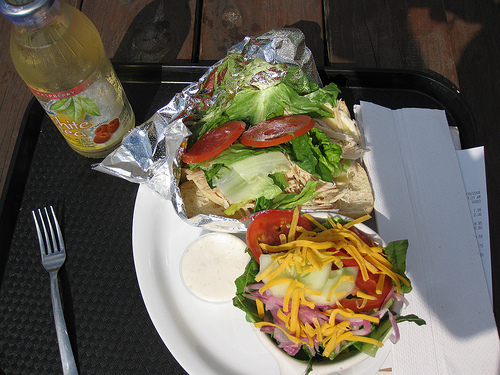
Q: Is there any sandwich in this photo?
A: Yes, there is a sandwich.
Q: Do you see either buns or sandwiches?
A: Yes, there is a sandwich.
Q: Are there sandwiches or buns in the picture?
A: Yes, there is a sandwich.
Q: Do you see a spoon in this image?
A: No, there are no spoons.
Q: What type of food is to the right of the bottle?
A: The food is a sandwich.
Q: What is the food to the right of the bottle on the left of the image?
A: The food is a sandwich.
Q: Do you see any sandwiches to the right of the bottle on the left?
A: Yes, there is a sandwich to the right of the bottle.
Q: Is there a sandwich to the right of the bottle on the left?
A: Yes, there is a sandwich to the right of the bottle.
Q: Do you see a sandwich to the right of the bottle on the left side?
A: Yes, there is a sandwich to the right of the bottle.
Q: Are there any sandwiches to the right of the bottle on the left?
A: Yes, there is a sandwich to the right of the bottle.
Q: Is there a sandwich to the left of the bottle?
A: No, the sandwich is to the right of the bottle.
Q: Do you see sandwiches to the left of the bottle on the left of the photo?
A: No, the sandwich is to the right of the bottle.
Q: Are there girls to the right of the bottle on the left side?
A: No, there is a sandwich to the right of the bottle.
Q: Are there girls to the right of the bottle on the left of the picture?
A: No, there is a sandwich to the right of the bottle.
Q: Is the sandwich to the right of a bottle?
A: Yes, the sandwich is to the right of a bottle.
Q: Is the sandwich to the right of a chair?
A: No, the sandwich is to the right of a bottle.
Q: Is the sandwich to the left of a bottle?
A: No, the sandwich is to the right of a bottle.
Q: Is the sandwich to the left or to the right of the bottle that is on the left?
A: The sandwich is to the right of the bottle.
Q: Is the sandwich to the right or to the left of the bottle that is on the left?
A: The sandwich is to the right of the bottle.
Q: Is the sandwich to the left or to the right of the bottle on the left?
A: The sandwich is to the right of the bottle.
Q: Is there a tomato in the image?
A: Yes, there is a tomato.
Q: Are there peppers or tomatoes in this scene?
A: Yes, there is a tomato.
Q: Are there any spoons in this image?
A: No, there are no spoons.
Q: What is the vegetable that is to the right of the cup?
A: The vegetable is a tomato.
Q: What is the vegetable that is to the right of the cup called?
A: The vegetable is a tomato.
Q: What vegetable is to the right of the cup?
A: The vegetable is a tomato.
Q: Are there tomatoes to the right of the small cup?
A: Yes, there is a tomato to the right of the cup.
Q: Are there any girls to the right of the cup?
A: No, there is a tomato to the right of the cup.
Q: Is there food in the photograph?
A: Yes, there is food.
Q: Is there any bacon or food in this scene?
A: Yes, there is food.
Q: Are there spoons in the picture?
A: No, there are no spoons.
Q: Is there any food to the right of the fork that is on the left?
A: Yes, there is food to the right of the fork.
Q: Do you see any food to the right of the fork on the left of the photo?
A: Yes, there is food to the right of the fork.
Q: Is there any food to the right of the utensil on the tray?
A: Yes, there is food to the right of the fork.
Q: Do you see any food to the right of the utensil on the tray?
A: Yes, there is food to the right of the fork.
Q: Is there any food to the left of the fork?
A: No, the food is to the right of the fork.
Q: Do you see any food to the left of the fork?
A: No, the food is to the right of the fork.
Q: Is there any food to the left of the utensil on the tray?
A: No, the food is to the right of the fork.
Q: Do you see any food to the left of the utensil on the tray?
A: No, the food is to the right of the fork.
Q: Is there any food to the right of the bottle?
A: Yes, there is food to the right of the bottle.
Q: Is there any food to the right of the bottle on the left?
A: Yes, there is food to the right of the bottle.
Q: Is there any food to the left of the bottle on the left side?
A: No, the food is to the right of the bottle.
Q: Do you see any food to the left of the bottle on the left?
A: No, the food is to the right of the bottle.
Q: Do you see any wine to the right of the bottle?
A: No, there is food to the right of the bottle.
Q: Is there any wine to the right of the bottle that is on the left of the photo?
A: No, there is food to the right of the bottle.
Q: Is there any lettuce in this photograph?
A: Yes, there is lettuce.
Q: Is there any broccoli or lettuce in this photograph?
A: Yes, there is lettuce.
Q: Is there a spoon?
A: No, there are no spoons.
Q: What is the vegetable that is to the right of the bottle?
A: The vegetable is lettuce.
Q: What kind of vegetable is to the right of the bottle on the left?
A: The vegetable is lettuce.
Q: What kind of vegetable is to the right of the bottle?
A: The vegetable is lettuce.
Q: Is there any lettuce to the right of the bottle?
A: Yes, there is lettuce to the right of the bottle.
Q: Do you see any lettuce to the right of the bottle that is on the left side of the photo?
A: Yes, there is lettuce to the right of the bottle.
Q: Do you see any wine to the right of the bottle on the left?
A: No, there is lettuce to the right of the bottle.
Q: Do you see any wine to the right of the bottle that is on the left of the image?
A: No, there is lettuce to the right of the bottle.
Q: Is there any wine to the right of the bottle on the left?
A: No, there is lettuce to the right of the bottle.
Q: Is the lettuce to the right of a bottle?
A: Yes, the lettuce is to the right of a bottle.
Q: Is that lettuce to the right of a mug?
A: No, the lettuce is to the right of a bottle.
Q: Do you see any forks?
A: Yes, there is a fork.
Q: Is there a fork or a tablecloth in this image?
A: Yes, there is a fork.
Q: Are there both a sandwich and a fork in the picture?
A: Yes, there are both a fork and a sandwich.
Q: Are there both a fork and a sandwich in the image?
A: Yes, there are both a fork and a sandwich.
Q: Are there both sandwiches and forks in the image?
A: Yes, there are both a fork and a sandwich.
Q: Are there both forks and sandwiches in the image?
A: Yes, there are both a fork and a sandwich.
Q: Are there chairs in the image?
A: No, there are no chairs.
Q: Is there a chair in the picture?
A: No, there are no chairs.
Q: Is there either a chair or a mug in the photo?
A: No, there are no chairs or mugs.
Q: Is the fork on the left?
A: Yes, the fork is on the left of the image.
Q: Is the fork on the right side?
A: No, the fork is on the left of the image.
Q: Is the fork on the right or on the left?
A: The fork is on the left of the image.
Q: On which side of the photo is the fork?
A: The fork is on the left of the image.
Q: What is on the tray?
A: The fork is on the tray.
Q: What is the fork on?
A: The fork is on the tray.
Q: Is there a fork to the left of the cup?
A: Yes, there is a fork to the left of the cup.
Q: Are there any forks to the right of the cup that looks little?
A: No, the fork is to the left of the cup.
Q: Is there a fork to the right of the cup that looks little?
A: No, the fork is to the left of the cup.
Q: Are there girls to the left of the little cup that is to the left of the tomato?
A: No, there is a fork to the left of the cup.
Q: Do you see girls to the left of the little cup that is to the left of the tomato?
A: No, there is a fork to the left of the cup.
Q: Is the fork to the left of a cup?
A: Yes, the fork is to the left of a cup.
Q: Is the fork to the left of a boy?
A: No, the fork is to the left of a cup.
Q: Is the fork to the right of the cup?
A: No, the fork is to the left of the cup.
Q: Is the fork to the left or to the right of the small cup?
A: The fork is to the left of the cup.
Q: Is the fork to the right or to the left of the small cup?
A: The fork is to the left of the cup.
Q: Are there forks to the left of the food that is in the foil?
A: Yes, there is a fork to the left of the food.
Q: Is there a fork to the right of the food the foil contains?
A: No, the fork is to the left of the food.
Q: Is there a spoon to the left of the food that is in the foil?
A: No, there is a fork to the left of the food.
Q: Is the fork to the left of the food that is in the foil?
A: Yes, the fork is to the left of the food.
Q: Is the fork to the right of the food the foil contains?
A: No, the fork is to the left of the food.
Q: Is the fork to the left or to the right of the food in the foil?
A: The fork is to the left of the food.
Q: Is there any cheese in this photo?
A: Yes, there is cheese.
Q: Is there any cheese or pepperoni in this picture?
A: Yes, there is cheese.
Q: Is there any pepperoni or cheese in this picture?
A: Yes, there is cheese.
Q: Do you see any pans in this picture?
A: No, there are no pans.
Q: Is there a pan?
A: No, there are no pans.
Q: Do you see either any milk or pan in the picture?
A: No, there are no pans or milk.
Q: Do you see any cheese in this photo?
A: Yes, there is cheese.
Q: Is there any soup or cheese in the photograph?
A: Yes, there is cheese.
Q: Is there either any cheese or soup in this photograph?
A: Yes, there is cheese.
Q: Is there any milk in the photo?
A: No, there is no milk.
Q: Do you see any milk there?
A: No, there is no milk.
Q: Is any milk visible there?
A: No, there is no milk.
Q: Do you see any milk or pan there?
A: No, there are no milk or pans.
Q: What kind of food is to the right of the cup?
A: The food is cheese.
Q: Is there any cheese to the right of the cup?
A: Yes, there is cheese to the right of the cup.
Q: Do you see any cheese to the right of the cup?
A: Yes, there is cheese to the right of the cup.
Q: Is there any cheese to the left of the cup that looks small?
A: No, the cheese is to the right of the cup.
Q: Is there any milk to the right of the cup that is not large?
A: No, there is cheese to the right of the cup.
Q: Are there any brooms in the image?
A: No, there are no brooms.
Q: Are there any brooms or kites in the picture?
A: No, there are no brooms or kites.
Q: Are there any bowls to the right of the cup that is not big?
A: Yes, there is a bowl to the right of the cup.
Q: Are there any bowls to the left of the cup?
A: No, the bowl is to the right of the cup.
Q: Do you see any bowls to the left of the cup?
A: No, the bowl is to the right of the cup.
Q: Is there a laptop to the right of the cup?
A: No, there is a bowl to the right of the cup.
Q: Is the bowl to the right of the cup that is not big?
A: Yes, the bowl is to the right of the cup.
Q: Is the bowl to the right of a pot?
A: No, the bowl is to the right of the cup.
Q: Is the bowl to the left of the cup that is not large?
A: No, the bowl is to the right of the cup.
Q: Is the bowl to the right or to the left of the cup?
A: The bowl is to the right of the cup.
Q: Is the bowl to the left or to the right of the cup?
A: The bowl is to the right of the cup.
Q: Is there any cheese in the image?
A: Yes, there is cheese.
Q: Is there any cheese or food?
A: Yes, there is cheese.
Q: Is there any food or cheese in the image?
A: Yes, there is cheese.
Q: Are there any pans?
A: No, there are no pans.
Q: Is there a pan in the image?
A: No, there are no pans.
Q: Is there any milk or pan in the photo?
A: No, there are no pans or milk.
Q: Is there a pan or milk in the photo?
A: No, there are no pans or milk.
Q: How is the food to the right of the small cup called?
A: The food is cheese.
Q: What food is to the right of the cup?
A: The food is cheese.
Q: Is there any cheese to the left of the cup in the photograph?
A: No, the cheese is to the right of the cup.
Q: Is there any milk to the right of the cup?
A: No, there is cheese to the right of the cup.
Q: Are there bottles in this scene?
A: Yes, there is a bottle.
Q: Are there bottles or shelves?
A: Yes, there is a bottle.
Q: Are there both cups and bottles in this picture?
A: Yes, there are both a bottle and a cup.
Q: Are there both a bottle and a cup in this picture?
A: Yes, there are both a bottle and a cup.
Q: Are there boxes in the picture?
A: No, there are no boxes.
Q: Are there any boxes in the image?
A: No, there are no boxes.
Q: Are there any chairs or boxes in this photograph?
A: No, there are no boxes or chairs.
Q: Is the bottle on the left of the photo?
A: Yes, the bottle is on the left of the image.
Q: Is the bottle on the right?
A: No, the bottle is on the left of the image.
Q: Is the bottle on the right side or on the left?
A: The bottle is on the left of the image.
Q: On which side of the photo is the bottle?
A: The bottle is on the left of the image.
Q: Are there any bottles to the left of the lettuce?
A: Yes, there is a bottle to the left of the lettuce.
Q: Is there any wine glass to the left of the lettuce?
A: No, there is a bottle to the left of the lettuce.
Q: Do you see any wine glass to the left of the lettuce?
A: No, there is a bottle to the left of the lettuce.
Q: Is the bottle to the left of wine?
A: No, the bottle is to the left of the lettuce.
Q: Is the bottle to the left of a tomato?
A: Yes, the bottle is to the left of a tomato.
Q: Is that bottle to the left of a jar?
A: No, the bottle is to the left of a tomato.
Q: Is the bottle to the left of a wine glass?
A: No, the bottle is to the left of a tomato.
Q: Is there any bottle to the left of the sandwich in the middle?
A: Yes, there is a bottle to the left of the sandwich.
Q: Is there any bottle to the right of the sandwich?
A: No, the bottle is to the left of the sandwich.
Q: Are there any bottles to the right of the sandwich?
A: No, the bottle is to the left of the sandwich.